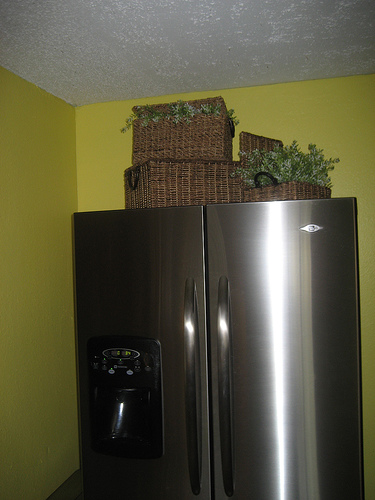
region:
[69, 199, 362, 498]
A silver refrigerator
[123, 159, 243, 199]
A large brown basket with handle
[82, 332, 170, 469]
Black oblong controls and pocket for glass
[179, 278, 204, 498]
Stainless steel handle on left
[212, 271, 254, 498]
A stainless steel handle on the right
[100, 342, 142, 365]
Green lights on refrigerator control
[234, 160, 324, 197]
Small brown basket with greenery in it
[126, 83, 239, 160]
Brown basket with lid and greenery sticking out of it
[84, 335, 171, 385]
Ice and water controls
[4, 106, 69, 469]
A yellow colored wall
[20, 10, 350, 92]
The ceiling is white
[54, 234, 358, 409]
The fridge is stainless steel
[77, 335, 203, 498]
A water and ice maker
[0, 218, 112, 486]
The wall is next to the fridge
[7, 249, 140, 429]
The wall is green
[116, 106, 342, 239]
Wicker baskets are atop the fridge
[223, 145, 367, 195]
The basket has a plant in it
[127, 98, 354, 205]
There are three baskets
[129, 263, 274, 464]
There are two doors on the fridge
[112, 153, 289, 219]
The basket is brown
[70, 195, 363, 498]
stainless steel two door refrigerator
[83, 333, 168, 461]
ice and water filter on front of fridge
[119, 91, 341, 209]
brown woven baskets on top of fridge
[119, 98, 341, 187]
green plants coming out of baskets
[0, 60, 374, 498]
yellow wall behind refrigerator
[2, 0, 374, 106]
white popcorn styled ceiling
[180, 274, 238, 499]
two long handles on door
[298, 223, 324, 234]
brand logo on fridge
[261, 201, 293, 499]
long glare from camera on fridge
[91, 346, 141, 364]
green lights on filter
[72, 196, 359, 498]
stainless steel refrigerator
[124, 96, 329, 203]
three decorative wicker baskets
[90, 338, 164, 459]
ice and water panel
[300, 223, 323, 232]
metal logo on the door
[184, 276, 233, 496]
two door handles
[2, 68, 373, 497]
walls are painted yellow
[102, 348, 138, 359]
lighted display is on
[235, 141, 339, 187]
artificial green plants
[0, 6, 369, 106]
popcorn ceiling is white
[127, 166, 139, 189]
wicker basket handle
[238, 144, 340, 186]
green plants in a basket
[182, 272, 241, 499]
double handles on a fridge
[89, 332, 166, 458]
an ice maker on a fridge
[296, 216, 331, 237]
logo on a fridge door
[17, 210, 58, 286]
yellow wall beside a fridge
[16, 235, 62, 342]
yellow wall in a kitchen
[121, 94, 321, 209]
a group of wicker baskets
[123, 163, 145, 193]
a handle on a basket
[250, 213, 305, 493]
a reflection on the fridge door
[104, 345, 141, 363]
a digital display on an ice maker